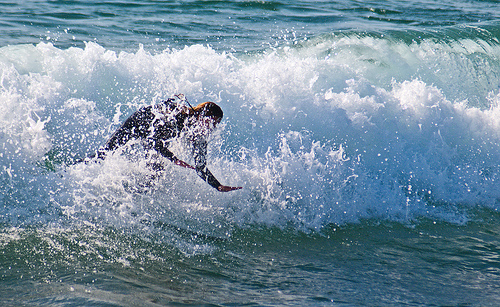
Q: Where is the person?
A: In the waves.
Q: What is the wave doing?
A: Crashing.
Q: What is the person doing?
A: Riding a wave.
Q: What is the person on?
A: A wave.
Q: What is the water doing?
A: Making a wave.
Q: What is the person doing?
A: Swimming in a wave.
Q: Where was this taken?
A: In the ocean.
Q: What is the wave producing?
A: Foam.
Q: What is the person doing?
A: Surfing on a wave.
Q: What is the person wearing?
A: A wetsuit.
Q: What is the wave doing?
A: Helping a surfer surf.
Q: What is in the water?
A: A surfer.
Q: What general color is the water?
A: Blue.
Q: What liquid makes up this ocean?
A: Water.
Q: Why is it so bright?
A: Sunny.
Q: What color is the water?
A: Green.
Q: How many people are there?
A: One.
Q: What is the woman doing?
A: Surfing.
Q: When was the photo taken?
A: Daytime.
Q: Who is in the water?
A: A woman.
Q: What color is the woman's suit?
A: Black.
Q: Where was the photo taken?
A: The ocean.